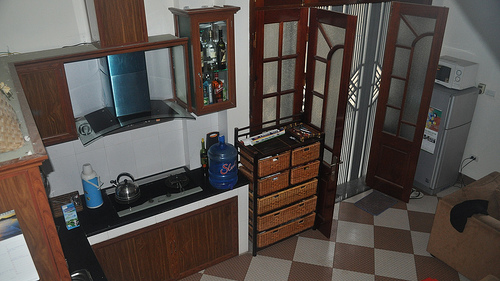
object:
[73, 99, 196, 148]
hood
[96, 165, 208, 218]
stove top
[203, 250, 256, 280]
shape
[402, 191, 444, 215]
diamond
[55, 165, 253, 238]
cooktop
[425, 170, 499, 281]
sofa chair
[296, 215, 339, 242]
shape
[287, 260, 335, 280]
shape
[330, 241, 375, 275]
shape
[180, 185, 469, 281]
floor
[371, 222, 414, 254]
diamond shape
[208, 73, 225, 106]
bottles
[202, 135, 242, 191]
bottles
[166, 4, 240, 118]
cabinet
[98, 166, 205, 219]
black stove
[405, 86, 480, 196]
refrigerator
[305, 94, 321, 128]
glass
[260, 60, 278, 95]
window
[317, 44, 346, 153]
window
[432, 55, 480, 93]
microwave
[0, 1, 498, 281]
kitchen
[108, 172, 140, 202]
kettle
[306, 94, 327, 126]
window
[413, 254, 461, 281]
shape